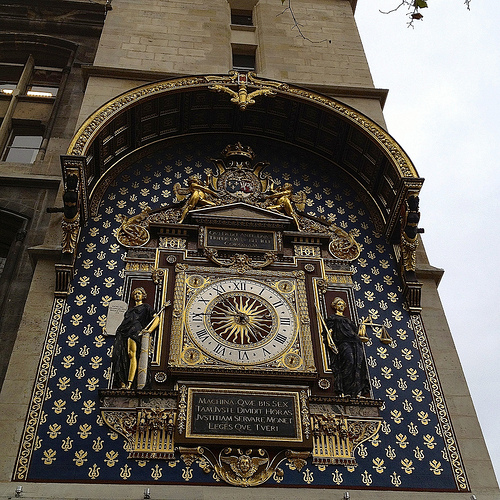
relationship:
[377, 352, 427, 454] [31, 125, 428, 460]
background has accents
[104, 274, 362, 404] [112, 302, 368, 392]
statues wear robes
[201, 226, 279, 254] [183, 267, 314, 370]
black plaque above clock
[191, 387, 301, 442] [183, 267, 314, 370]
black plaque above clock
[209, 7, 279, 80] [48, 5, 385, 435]
windows on building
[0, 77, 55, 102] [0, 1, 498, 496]
light inside building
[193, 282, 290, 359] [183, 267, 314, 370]
numerals on clock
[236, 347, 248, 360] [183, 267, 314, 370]
numerals on clock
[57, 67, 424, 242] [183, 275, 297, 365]
arch on clock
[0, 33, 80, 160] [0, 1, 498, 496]
window on building